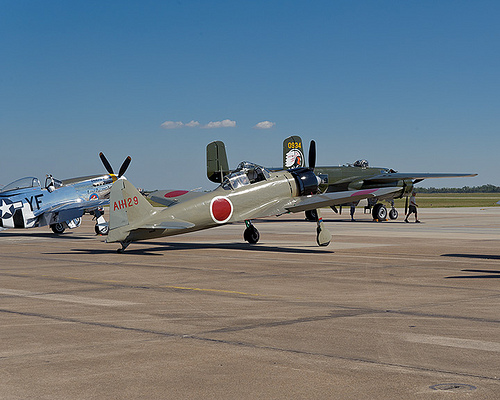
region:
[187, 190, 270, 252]
red circle on green plane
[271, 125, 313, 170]
native american on tail of plane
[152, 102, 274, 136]
small clouds in blue sky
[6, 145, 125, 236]
blue plane with white and black stripe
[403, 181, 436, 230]
man under plane on tarmack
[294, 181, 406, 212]
red stripe on grey plane wing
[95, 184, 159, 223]
red lettering on grey plane tail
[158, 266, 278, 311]
yellow stripe on tarmack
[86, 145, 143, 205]
propeller on blue plane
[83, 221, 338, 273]
shadow of plane on tarmack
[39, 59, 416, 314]
these are airplanes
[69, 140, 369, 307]
these are military planes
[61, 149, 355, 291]
this is an airforce plane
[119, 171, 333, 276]
the plane is olive green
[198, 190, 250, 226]
this is a red dot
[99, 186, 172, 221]
the tail says AH29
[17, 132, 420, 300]
there are three planes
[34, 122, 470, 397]
this is on a runway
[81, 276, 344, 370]
the runway is light gray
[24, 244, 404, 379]
the runway is made of pavement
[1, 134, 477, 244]
Planes parked on a cement lot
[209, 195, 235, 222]
A red and white dot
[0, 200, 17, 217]
A blue and white star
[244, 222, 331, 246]
The wheels of the green plane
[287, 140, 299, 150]
Yellow numbers on a plane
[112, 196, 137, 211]
Red numbers on the plane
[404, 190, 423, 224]
A man walking by the plane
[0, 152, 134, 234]
A silver plane with blue paint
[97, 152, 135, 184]
The front rudder of the plane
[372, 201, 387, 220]
A large plane wheel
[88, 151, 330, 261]
plane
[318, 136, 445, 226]
black plane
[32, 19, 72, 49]
white clouds in blue sky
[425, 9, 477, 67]
white clouds in blue sky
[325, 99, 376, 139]
white clouds in blue sky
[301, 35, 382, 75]
white clouds in blue sky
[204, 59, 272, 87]
white clouds in blue sky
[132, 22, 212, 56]
white clouds in blue sky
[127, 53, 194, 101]
white clouds in blue sky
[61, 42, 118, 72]
white clouds in blue sky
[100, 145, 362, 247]
An olive colored military aircraft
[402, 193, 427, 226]
A man dressed in a white shirt walking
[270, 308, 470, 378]
Gray colored concrete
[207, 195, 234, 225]
A circle colored red with a white outline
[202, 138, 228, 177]
A green airplane tale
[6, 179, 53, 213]
The letters YF on the side of an airplane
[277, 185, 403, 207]
An airplane wing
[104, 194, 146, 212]
The insignia AHH29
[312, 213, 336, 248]
Part of an airplane landing gear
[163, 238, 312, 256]
The long dark shadow of an aircraft